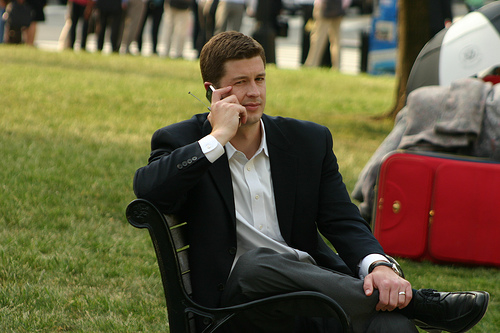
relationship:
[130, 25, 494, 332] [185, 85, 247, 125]
man holding phone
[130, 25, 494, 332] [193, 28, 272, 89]
man has hair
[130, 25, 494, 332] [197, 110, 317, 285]
man wears shirt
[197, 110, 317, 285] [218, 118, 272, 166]
shirt has collar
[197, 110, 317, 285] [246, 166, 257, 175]
shirt has button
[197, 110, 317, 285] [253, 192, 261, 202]
shirt has button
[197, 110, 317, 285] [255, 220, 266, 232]
shirt has button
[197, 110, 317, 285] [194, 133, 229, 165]
shirt has cuff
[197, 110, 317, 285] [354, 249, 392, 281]
shirt has cuff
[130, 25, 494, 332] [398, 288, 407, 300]
man wears ring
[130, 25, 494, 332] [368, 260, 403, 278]
man wears watch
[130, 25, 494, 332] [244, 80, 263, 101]
man has nose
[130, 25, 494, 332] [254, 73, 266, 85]
man has eye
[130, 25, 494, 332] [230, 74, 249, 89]
man has eye